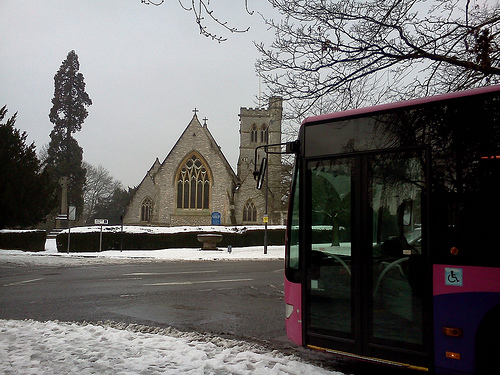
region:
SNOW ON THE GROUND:
[15, 318, 263, 369]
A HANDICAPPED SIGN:
[441, 262, 469, 293]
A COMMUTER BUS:
[264, 81, 492, 369]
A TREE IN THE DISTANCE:
[36, 43, 95, 245]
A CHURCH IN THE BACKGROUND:
[116, 91, 294, 230]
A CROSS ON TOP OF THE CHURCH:
[186, 101, 205, 120]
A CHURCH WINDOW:
[164, 146, 224, 216]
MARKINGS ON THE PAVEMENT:
[119, 258, 273, 299]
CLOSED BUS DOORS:
[295, 143, 443, 370]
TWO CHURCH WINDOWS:
[242, 116, 282, 156]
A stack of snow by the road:
[8, 322, 180, 369]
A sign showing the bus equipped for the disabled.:
[431, 266, 473, 292]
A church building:
[118, 93, 249, 233]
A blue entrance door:
[208, 213, 223, 224]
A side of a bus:
[275, 102, 440, 353]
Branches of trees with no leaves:
[273, 5, 456, 89]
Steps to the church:
[38, 225, 66, 250]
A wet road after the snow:
[21, 264, 246, 326]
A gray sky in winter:
[111, 25, 161, 120]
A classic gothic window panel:
[175, 153, 215, 210]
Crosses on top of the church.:
[190, 103, 210, 125]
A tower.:
[236, 100, 281, 185]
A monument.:
[47, 170, 72, 236]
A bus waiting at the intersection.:
[2, 70, 497, 365]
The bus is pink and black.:
[280, 80, 495, 370]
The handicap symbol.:
[440, 260, 465, 290]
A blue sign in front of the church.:
[210, 210, 220, 225]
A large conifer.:
[40, 45, 91, 237]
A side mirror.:
[246, 140, 276, 186]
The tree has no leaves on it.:
[270, 5, 485, 92]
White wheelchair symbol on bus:
[442, 263, 464, 288]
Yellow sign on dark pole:
[260, 212, 270, 252]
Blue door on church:
[210, 208, 218, 224]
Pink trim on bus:
[430, 261, 497, 296]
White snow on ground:
[0, 316, 290, 369]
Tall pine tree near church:
[46, 45, 88, 216]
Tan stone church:
[121, 95, 287, 221]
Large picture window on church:
[172, 146, 214, 212]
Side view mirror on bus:
[246, 137, 297, 187]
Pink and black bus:
[281, 80, 498, 370]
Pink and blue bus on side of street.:
[259, 88, 495, 371]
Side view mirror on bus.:
[252, 135, 291, 188]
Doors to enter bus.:
[306, 151, 438, 368]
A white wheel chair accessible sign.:
[439, 259, 467, 296]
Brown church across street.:
[113, 93, 300, 228]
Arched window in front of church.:
[165, 148, 220, 217]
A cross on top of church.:
[186, 103, 204, 121]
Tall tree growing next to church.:
[40, 53, 94, 220]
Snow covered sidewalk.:
[26, 318, 206, 372]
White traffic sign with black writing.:
[62, 204, 119, 254]